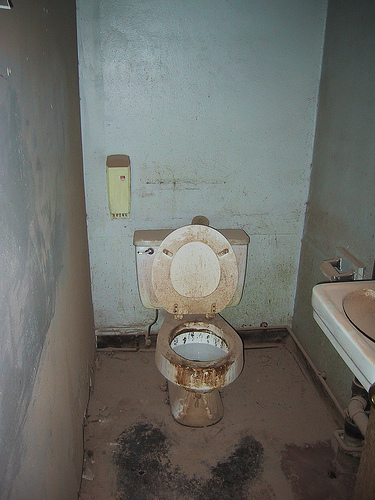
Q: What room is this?
A: Bathroom.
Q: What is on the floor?
A: Toilet.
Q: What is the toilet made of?
A: Ceramic.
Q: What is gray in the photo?
A: Walls.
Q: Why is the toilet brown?
A: It is filthy.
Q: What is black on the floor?
A: Stains.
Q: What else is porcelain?
A: The sink.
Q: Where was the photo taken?
A: In the bathroom.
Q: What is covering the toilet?
A: Dirt.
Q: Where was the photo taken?
A: The bathroom.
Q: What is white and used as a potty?
A: Toilet bowl.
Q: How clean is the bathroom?
A: Very dirty.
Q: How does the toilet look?
A: Dirty.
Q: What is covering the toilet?
A: Dirt.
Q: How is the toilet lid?
A: Open.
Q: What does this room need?
A: Cleaning.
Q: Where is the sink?
A: To the right of the room.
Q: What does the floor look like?
A: Dirty.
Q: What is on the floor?
A: Dirt spots.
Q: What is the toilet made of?
A: Porcelain.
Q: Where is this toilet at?
A: Bathroom.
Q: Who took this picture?
A: Health Inspector.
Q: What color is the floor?
A: Brown.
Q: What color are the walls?
A: Teal.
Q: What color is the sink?
A: White.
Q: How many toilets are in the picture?
A: One.